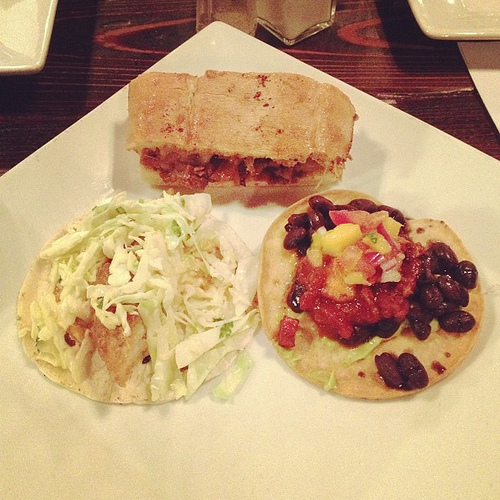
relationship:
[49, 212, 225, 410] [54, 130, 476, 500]
tortilla on plate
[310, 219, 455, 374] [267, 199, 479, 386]
beans on tortilla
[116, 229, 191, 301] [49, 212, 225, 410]
lettuce on tortilla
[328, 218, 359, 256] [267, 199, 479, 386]
pineapple on tortilla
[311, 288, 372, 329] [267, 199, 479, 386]
salsa on tortilla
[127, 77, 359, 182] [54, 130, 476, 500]
bread on plate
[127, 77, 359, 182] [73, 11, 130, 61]
bread on table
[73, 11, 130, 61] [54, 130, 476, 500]
table below plate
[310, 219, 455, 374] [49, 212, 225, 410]
beans on tortilla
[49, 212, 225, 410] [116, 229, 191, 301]
tortilla with lettuce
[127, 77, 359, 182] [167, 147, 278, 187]
bread has meat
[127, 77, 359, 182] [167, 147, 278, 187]
bread with meat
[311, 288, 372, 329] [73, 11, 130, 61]
salsa on table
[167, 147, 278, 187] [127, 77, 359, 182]
meat in bread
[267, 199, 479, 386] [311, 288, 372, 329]
tortilla with salsa